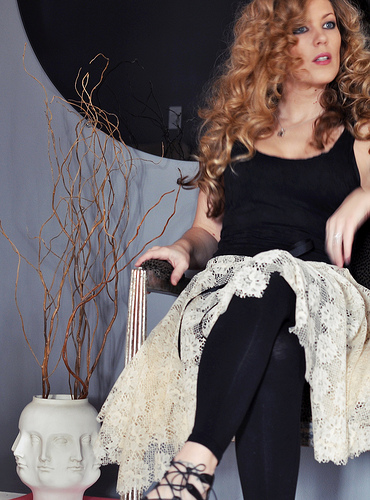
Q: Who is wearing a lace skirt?
A: Woman in chair.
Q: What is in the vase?
A: Sticks.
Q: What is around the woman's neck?
A: A necklace.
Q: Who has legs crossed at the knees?
A: The woman.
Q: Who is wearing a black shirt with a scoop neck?
A: The woman.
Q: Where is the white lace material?
A: Draped around the woman.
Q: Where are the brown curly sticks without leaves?
A: To the left of the woman.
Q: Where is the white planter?
A: On the floor.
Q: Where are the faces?
A: On the white planter.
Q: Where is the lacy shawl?
A: Across the woman's knees.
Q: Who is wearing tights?
A: The woman.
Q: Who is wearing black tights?
A: The woman.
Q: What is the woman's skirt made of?
A: White lace.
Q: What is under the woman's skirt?
A: Black leggings.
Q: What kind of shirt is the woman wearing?
A: Black tank top.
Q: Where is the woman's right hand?
A: On the arm rest.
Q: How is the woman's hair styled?
A: Curly light-brown hair, worn down.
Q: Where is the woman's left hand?
A: Hanging off arm rest.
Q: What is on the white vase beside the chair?
A: Multiple faces.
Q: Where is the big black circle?
A: Behind woman's head.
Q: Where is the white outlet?
A: On black wall.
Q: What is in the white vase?
A: Dried branches.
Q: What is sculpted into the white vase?
A: Faces.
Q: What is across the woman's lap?
A: Lace material.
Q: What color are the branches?
A: Brown.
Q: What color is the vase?
A: White.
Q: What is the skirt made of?
A: Lace.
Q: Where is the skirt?
A: On the Woman.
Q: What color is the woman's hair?
A: Red.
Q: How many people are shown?
A: One.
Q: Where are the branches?
A: The Vase.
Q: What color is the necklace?
A: Silver.